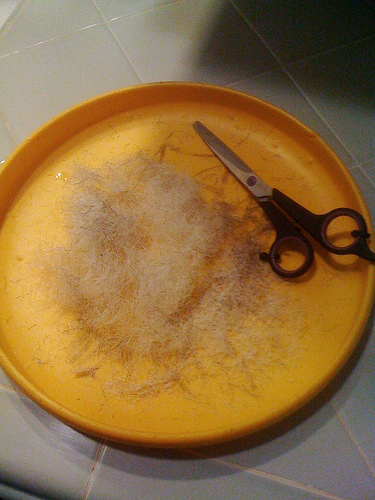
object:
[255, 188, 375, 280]
handle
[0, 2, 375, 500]
floor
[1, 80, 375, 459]
plate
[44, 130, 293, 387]
hairs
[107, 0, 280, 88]
tiles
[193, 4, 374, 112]
shadow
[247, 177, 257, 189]
screw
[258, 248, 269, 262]
notch